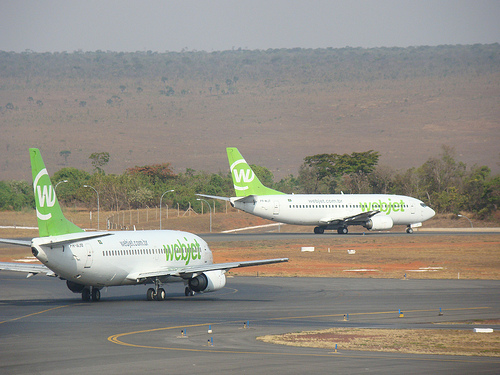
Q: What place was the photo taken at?
A: It was taken at the airport.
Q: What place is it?
A: It is an airport.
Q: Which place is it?
A: It is an airport.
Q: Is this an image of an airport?
A: Yes, it is showing an airport.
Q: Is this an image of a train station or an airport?
A: It is showing an airport.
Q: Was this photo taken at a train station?
A: No, the picture was taken in an airport.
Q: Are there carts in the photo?
A: No, there are no carts.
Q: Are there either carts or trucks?
A: No, there are no carts or trucks.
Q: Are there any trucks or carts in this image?
A: No, there are no carts or trucks.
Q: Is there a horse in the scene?
A: No, there are no horses.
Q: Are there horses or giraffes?
A: No, there are no horses or giraffes.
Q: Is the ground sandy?
A: Yes, the ground is sandy.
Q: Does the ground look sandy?
A: Yes, the ground is sandy.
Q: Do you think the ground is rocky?
A: No, the ground is sandy.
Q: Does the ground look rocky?
A: No, the ground is sandy.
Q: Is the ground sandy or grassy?
A: The ground is sandy.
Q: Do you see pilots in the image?
A: No, there are no pilots.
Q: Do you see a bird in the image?
A: No, there are no birds.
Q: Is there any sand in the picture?
A: Yes, there is sand.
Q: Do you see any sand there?
A: Yes, there is sand.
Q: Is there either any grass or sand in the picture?
A: Yes, there is sand.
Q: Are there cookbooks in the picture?
A: No, there are no cookbooks.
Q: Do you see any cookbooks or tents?
A: No, there are no cookbooks or tents.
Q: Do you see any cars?
A: No, there are no cars.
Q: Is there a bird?
A: No, there are no birds.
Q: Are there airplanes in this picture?
A: Yes, there are airplanes.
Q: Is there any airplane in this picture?
A: Yes, there are airplanes.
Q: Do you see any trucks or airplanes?
A: Yes, there are airplanes.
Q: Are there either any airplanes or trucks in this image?
A: Yes, there are airplanes.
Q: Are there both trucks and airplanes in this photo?
A: No, there are airplanes but no trucks.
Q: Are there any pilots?
A: No, there are no pilots.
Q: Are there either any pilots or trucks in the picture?
A: No, there are no pilots or trucks.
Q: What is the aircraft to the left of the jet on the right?
A: The aircraft is airplanes.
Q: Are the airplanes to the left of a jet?
A: Yes, the airplanes are to the left of a jet.